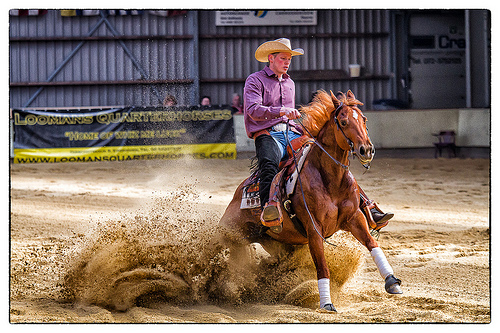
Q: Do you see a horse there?
A: Yes, there is a horse.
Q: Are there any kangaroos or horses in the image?
A: Yes, there is a horse.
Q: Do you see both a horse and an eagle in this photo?
A: No, there is a horse but no eagles.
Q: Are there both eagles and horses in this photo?
A: No, there is a horse but no eagles.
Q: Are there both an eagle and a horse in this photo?
A: No, there is a horse but no eagles.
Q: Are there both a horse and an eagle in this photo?
A: No, there is a horse but no eagles.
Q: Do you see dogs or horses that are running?
A: Yes, the horse is running.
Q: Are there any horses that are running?
A: Yes, there is a horse that is running.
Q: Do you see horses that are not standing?
A: Yes, there is a horse that is running .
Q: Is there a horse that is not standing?
A: Yes, there is a horse that is running.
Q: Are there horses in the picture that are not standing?
A: Yes, there is a horse that is running.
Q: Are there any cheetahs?
A: No, there are no cheetahs.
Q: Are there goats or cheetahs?
A: No, there are no cheetahs or goats.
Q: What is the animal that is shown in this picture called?
A: The animal is a horse.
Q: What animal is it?
A: The animal is a horse.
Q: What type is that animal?
A: This is a horse.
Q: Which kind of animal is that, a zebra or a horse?
A: This is a horse.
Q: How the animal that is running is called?
A: The animal is a horse.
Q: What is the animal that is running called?
A: The animal is a horse.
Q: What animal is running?
A: The animal is a horse.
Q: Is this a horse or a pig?
A: This is a horse.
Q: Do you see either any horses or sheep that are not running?
A: No, there is a horse but it is running.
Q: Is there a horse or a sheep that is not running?
A: No, there is a horse but it is running.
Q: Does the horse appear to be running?
A: Yes, the horse is running.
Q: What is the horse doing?
A: The horse is running.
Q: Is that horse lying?
A: No, the horse is running.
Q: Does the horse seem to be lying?
A: No, the horse is running.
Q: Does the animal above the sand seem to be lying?
A: No, the horse is running.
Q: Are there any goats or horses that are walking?
A: No, there is a horse but it is running.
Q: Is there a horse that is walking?
A: No, there is a horse but it is running.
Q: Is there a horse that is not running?
A: No, there is a horse but it is running.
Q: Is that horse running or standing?
A: The horse is running.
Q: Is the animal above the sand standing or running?
A: The horse is running.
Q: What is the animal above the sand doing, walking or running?
A: The horse is running.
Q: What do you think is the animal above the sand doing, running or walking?
A: The horse is running.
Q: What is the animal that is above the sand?
A: The animal is a horse.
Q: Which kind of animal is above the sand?
A: The animal is a horse.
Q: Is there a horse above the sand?
A: Yes, there is a horse above the sand.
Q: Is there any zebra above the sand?
A: No, there is a horse above the sand.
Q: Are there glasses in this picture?
A: No, there are no glasses.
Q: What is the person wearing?
A: The person is wearing a cowboy hat.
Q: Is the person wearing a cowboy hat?
A: Yes, the person is wearing a cowboy hat.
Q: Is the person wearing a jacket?
A: No, the person is wearing a cowboy hat.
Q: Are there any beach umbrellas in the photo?
A: No, there are no beach umbrellas.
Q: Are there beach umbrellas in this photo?
A: No, there are no beach umbrellas.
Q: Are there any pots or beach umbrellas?
A: No, there are no beach umbrellas or pots.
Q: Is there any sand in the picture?
A: Yes, there is sand.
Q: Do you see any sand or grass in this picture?
A: Yes, there is sand.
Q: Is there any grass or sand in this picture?
A: Yes, there is sand.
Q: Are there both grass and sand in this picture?
A: No, there is sand but no grass.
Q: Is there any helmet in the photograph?
A: No, there are no helmets.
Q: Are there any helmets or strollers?
A: No, there are no helmets or strollers.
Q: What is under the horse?
A: The sand is under the horse.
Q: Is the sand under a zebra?
A: No, the sand is under the horse.